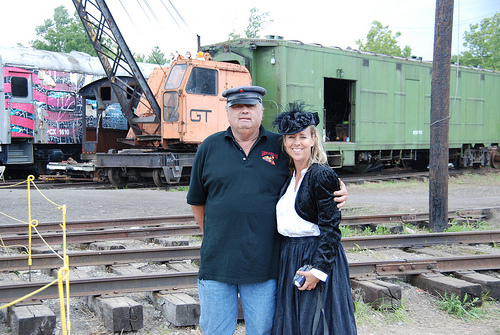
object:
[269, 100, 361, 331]
woman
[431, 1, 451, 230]
pole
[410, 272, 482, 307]
block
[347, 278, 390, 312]
block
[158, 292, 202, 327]
block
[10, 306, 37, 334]
block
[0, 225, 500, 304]
track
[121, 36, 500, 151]
train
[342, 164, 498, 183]
train track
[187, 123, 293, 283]
black shirt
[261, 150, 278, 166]
logo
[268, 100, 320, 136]
hat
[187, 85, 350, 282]
man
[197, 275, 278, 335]
jeans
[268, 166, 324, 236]
shirt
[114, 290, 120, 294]
button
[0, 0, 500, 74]
sky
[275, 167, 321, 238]
blouse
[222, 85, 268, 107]
black hat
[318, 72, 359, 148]
open door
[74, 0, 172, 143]
crane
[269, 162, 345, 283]
jacket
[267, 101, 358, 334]
lady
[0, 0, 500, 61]
clouds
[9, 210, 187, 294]
sets